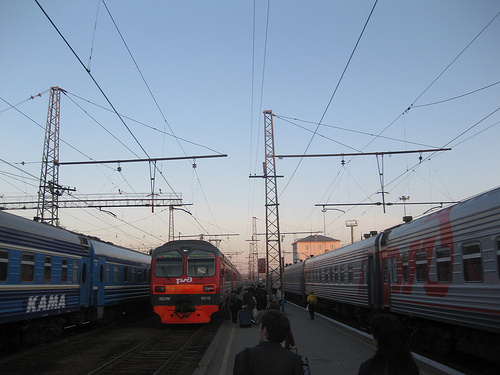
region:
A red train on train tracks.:
[150, 239, 242, 331]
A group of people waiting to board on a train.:
[225, 272, 268, 330]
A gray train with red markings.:
[287, 185, 496, 330]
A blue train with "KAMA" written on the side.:
[2, 205, 147, 330]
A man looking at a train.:
[231, 308, 301, 374]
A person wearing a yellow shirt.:
[305, 289, 320, 320]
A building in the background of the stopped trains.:
[291, 231, 339, 259]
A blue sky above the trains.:
[9, 15, 497, 145]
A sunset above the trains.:
[14, 108, 491, 262]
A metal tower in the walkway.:
[260, 106, 295, 323]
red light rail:
[140, 229, 261, 362]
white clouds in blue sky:
[108, 31, 143, 73]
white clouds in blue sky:
[186, 37, 255, 82]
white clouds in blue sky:
[109, 99, 149, 141]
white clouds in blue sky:
[330, 45, 413, 108]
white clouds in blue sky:
[277, 104, 330, 137]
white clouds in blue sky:
[404, 106, 458, 125]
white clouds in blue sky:
[429, 156, 469, 182]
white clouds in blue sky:
[54, 11, 107, 56]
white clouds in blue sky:
[168, 37, 206, 75]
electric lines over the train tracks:
[1, 1, 499, 249]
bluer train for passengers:
[0, 207, 146, 329]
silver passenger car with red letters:
[277, 198, 499, 325]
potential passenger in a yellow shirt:
[303, 284, 327, 323]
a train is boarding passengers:
[145, 241, 275, 347]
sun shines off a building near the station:
[282, 228, 368, 267]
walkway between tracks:
[233, 278, 442, 373]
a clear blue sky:
[3, 0, 498, 196]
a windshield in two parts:
[152, 250, 219, 285]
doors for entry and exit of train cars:
[77, 250, 112, 315]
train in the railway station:
[151, 232, 250, 325]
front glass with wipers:
[154, 255, 219, 283]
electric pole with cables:
[257, 98, 299, 316]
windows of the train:
[15, 253, 82, 279]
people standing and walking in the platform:
[242, 278, 284, 373]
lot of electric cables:
[59, 36, 234, 233]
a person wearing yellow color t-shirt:
[307, 291, 319, 306]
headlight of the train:
[151, 282, 221, 295]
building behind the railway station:
[286, 229, 333, 256]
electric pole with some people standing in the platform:
[237, 108, 294, 336]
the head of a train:
[156, 253, 213, 323]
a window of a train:
[158, 253, 171, 277]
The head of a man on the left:
[263, 317, 290, 339]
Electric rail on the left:
[47, 92, 59, 176]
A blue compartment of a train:
[14, 254, 89, 316]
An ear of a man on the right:
[263, 328, 270, 336]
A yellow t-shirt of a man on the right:
[310, 295, 316, 297]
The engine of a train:
[154, 300, 215, 322]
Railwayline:
[149, 341, 182, 373]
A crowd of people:
[237, 293, 271, 315]